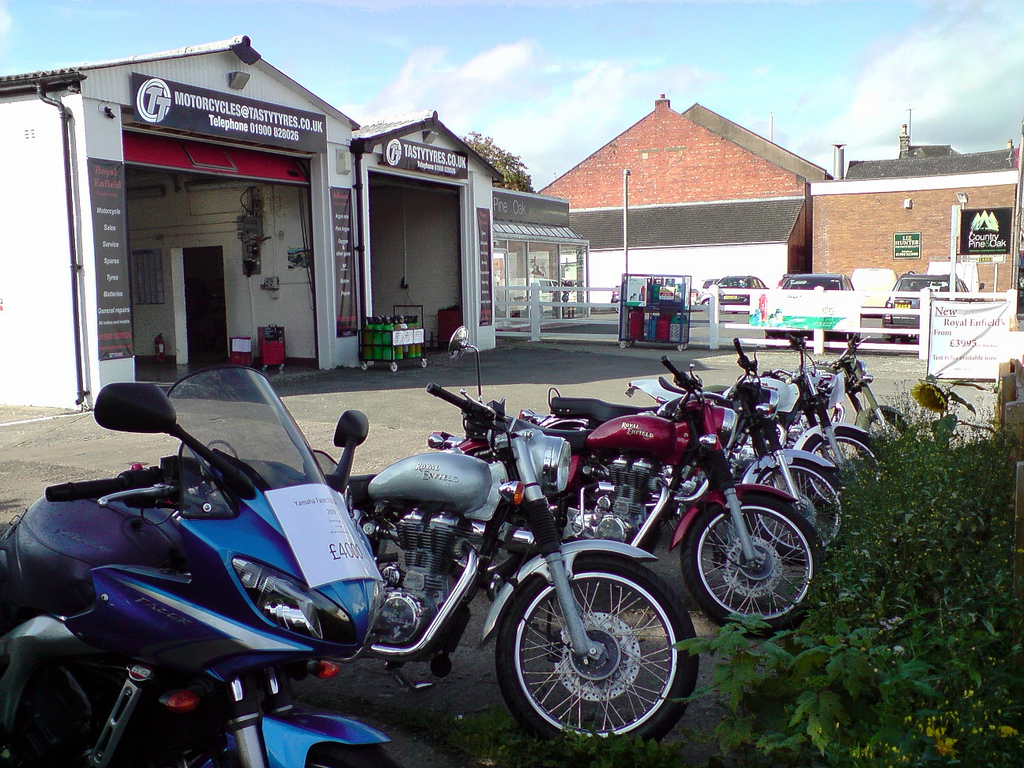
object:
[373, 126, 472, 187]
signboard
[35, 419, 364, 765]
blue bike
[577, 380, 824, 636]
red bike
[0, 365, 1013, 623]
road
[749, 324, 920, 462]
bike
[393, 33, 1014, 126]
clouds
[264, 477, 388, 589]
paper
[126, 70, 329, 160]
banner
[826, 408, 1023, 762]
bushes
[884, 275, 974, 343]
cars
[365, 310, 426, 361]
canisters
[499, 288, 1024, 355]
fence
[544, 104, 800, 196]
brick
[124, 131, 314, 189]
garage door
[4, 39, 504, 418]
house